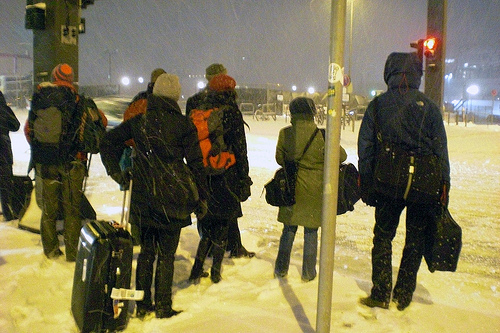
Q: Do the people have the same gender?
A: No, they are both male and female.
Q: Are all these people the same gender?
A: No, they are both male and female.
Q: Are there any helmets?
A: No, there are no helmets.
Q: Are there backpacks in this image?
A: Yes, there is a backpack.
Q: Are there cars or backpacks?
A: Yes, there is a backpack.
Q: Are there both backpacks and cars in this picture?
A: No, there is a backpack but no cars.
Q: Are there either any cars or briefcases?
A: No, there are no cars or briefcases.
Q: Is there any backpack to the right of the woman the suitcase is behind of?
A: Yes, there is a backpack to the right of the woman.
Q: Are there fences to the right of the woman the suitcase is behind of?
A: No, there is a backpack to the right of the woman.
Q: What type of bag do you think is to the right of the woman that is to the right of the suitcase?
A: The bag is a backpack.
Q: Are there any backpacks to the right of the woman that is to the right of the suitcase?
A: Yes, there is a backpack to the right of the woman.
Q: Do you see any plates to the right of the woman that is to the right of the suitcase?
A: No, there is a backpack to the right of the woman.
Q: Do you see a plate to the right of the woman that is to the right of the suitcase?
A: No, there is a backpack to the right of the woman.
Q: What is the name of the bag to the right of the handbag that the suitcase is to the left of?
A: The bag is a backpack.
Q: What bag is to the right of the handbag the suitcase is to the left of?
A: The bag is a backpack.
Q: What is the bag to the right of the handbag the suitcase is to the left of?
A: The bag is a backpack.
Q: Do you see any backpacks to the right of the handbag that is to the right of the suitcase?
A: Yes, there is a backpack to the right of the handbag.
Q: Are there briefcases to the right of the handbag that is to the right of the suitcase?
A: No, there is a backpack to the right of the handbag.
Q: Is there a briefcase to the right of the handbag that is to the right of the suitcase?
A: No, there is a backpack to the right of the handbag.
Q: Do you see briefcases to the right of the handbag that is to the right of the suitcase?
A: No, there is a backpack to the right of the handbag.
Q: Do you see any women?
A: Yes, there is a woman.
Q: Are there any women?
A: Yes, there is a woman.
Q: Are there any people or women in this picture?
A: Yes, there is a woman.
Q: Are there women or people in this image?
A: Yes, there is a woman.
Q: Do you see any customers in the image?
A: No, there are no customers.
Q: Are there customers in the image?
A: No, there are no customers.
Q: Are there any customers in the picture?
A: No, there are no customers.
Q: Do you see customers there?
A: No, there are no customers.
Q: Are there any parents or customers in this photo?
A: No, there are no customers or parents.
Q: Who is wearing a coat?
A: The woman is wearing a coat.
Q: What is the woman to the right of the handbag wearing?
A: The woman is wearing a coat.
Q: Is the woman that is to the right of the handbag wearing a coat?
A: Yes, the woman is wearing a coat.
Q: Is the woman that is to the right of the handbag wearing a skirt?
A: No, the woman is wearing a coat.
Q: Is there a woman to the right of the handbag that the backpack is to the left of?
A: Yes, there is a woman to the right of the handbag.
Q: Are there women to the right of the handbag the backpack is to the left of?
A: Yes, there is a woman to the right of the handbag.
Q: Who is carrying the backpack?
A: The woman is carrying the backpack.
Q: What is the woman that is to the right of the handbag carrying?
A: The woman is carrying a backpack.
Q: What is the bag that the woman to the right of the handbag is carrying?
A: The bag is a backpack.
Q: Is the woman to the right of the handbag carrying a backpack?
A: Yes, the woman is carrying a backpack.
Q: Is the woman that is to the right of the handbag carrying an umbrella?
A: No, the woman is carrying a backpack.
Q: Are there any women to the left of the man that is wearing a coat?
A: Yes, there is a woman to the left of the man.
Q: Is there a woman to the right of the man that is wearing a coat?
A: No, the woman is to the left of the man.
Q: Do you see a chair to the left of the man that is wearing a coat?
A: No, there is a woman to the left of the man.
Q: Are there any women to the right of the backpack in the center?
A: Yes, there is a woman to the right of the backpack.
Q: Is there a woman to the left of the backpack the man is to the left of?
A: No, the woman is to the right of the backpack.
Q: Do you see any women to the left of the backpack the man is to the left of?
A: No, the woman is to the right of the backpack.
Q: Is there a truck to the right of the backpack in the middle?
A: No, there is a woman to the right of the backpack.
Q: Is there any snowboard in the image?
A: No, there are no snowboards.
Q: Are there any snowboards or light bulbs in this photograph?
A: No, there are no snowboards or light bulbs.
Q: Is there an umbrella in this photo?
A: No, there are no umbrellas.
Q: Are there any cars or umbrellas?
A: No, there are no umbrellas or cars.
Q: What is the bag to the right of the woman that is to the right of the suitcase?
A: The bag is a handbag.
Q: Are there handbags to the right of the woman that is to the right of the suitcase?
A: Yes, there is a handbag to the right of the woman.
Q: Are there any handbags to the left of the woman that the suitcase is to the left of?
A: No, the handbag is to the right of the woman.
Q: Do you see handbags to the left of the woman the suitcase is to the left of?
A: No, the handbag is to the right of the woman.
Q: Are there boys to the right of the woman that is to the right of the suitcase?
A: No, there is a handbag to the right of the woman.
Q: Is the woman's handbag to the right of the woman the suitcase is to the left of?
A: Yes, the handbag is to the right of the woman.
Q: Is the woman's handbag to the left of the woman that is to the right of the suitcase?
A: No, the handbag is to the right of the woman.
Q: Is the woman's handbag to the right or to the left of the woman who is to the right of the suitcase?
A: The handbag is to the right of the woman.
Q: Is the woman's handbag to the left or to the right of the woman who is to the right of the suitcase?
A: The handbag is to the right of the woman.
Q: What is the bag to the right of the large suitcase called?
A: The bag is a handbag.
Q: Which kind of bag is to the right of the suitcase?
A: The bag is a handbag.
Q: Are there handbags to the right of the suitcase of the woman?
A: Yes, there is a handbag to the right of the suitcase.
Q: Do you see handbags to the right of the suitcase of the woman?
A: Yes, there is a handbag to the right of the suitcase.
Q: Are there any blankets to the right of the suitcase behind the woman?
A: No, there is a handbag to the right of the suitcase.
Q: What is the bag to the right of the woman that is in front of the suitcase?
A: The bag is a handbag.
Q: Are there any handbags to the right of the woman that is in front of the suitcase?
A: Yes, there is a handbag to the right of the woman.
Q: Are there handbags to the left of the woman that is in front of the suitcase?
A: No, the handbag is to the right of the woman.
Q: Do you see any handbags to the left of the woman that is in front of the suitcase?
A: No, the handbag is to the right of the woman.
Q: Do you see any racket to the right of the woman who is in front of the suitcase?
A: No, there is a handbag to the right of the woman.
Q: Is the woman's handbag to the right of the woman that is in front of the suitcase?
A: Yes, the handbag is to the right of the woman.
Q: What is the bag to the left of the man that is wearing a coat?
A: The bag is a handbag.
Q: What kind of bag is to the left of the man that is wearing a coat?
A: The bag is a handbag.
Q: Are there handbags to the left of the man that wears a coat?
A: Yes, there is a handbag to the left of the man.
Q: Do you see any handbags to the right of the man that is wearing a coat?
A: No, the handbag is to the left of the man.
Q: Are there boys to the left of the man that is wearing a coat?
A: No, there is a handbag to the left of the man.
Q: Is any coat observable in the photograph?
A: Yes, there is a coat.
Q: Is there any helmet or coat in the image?
A: Yes, there is a coat.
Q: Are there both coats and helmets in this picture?
A: No, there is a coat but no helmets.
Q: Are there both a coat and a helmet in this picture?
A: No, there is a coat but no helmets.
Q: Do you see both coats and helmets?
A: No, there is a coat but no helmets.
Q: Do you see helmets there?
A: No, there are no helmets.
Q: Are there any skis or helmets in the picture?
A: No, there are no helmets or skis.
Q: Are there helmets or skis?
A: No, there are no helmets or skis.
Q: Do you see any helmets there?
A: No, there are no helmets.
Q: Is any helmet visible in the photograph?
A: No, there are no helmets.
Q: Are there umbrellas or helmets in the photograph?
A: No, there are no helmets or umbrellas.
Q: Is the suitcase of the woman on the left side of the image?
A: Yes, the suitcase is on the left of the image.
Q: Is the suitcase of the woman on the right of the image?
A: No, the suitcase is on the left of the image.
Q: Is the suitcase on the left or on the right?
A: The suitcase is on the left of the image.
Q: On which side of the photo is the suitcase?
A: The suitcase is on the left of the image.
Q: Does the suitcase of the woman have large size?
A: Yes, the suitcase is large.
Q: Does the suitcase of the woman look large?
A: Yes, the suitcase is large.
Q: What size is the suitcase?
A: The suitcase is large.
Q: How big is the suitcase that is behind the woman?
A: The suitcase is large.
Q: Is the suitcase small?
A: No, the suitcase is large.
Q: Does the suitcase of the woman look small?
A: No, the suitcase is large.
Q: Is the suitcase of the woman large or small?
A: The suitcase is large.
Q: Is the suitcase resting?
A: Yes, the suitcase is resting.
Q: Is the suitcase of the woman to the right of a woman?
A: No, the suitcase is to the left of a woman.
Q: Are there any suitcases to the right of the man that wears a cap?
A: Yes, there is a suitcase to the right of the man.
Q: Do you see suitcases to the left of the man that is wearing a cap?
A: No, the suitcase is to the right of the man.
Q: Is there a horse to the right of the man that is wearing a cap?
A: No, there is a suitcase to the right of the man.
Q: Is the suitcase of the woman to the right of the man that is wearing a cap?
A: Yes, the suitcase is to the right of the man.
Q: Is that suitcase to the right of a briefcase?
A: No, the suitcase is to the right of the man.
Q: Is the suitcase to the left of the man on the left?
A: No, the suitcase is to the right of the man.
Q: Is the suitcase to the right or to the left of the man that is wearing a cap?
A: The suitcase is to the right of the man.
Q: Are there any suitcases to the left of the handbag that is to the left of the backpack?
A: Yes, there is a suitcase to the left of the handbag.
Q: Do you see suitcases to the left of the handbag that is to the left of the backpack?
A: Yes, there is a suitcase to the left of the handbag.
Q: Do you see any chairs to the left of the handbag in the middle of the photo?
A: No, there is a suitcase to the left of the handbag.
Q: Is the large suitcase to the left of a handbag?
A: Yes, the suitcase is to the left of a handbag.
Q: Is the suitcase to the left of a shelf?
A: No, the suitcase is to the left of a handbag.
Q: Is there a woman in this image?
A: Yes, there is a woman.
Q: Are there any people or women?
A: Yes, there is a woman.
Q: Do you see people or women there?
A: Yes, there is a woman.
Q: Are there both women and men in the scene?
A: Yes, there are both a woman and a man.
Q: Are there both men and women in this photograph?
A: Yes, there are both a woman and a man.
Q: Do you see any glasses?
A: No, there are no glasses.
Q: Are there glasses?
A: No, there are no glasses.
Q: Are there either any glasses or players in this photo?
A: No, there are no glasses or players.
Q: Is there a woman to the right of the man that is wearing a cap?
A: Yes, there is a woman to the right of the man.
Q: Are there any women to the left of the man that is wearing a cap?
A: No, the woman is to the right of the man.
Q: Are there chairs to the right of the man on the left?
A: No, there is a woman to the right of the man.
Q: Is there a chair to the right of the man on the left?
A: No, there is a woman to the right of the man.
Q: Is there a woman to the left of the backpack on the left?
A: No, the woman is to the right of the backpack.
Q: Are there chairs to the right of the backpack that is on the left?
A: No, there is a woman to the right of the backpack.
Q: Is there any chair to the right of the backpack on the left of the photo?
A: No, there is a woman to the right of the backpack.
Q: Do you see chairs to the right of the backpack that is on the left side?
A: No, there is a woman to the right of the backpack.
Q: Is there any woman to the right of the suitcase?
A: Yes, there is a woman to the right of the suitcase.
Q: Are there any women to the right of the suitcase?
A: Yes, there is a woman to the right of the suitcase.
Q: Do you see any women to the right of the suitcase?
A: Yes, there is a woman to the right of the suitcase.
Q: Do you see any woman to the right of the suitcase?
A: Yes, there is a woman to the right of the suitcase.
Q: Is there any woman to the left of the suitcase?
A: No, the woman is to the right of the suitcase.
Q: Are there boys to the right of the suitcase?
A: No, there is a woman to the right of the suitcase.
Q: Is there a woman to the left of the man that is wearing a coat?
A: Yes, there is a woman to the left of the man.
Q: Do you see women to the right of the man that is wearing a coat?
A: No, the woman is to the left of the man.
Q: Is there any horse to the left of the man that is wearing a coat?
A: No, there is a woman to the left of the man.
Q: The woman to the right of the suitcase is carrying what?
A: The woman is carrying a backpack.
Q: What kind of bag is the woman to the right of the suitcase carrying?
A: The woman is carrying a backpack.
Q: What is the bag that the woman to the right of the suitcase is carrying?
A: The bag is a backpack.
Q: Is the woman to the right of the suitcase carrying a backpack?
A: Yes, the woman is carrying a backpack.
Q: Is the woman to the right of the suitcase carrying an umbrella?
A: No, the woman is carrying a backpack.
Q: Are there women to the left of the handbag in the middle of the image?
A: Yes, there is a woman to the left of the handbag.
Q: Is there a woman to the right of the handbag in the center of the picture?
A: No, the woman is to the left of the handbag.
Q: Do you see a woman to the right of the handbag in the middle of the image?
A: No, the woman is to the left of the handbag.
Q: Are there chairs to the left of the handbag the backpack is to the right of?
A: No, there is a woman to the left of the handbag.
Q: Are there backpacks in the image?
A: Yes, there is a backpack.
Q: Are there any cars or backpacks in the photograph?
A: Yes, there is a backpack.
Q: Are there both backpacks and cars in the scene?
A: No, there is a backpack but no cars.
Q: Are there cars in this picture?
A: No, there are no cars.